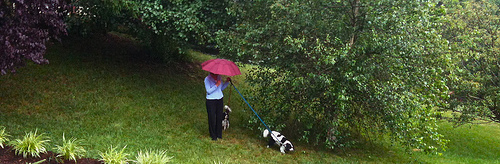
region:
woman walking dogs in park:
[20, 15, 477, 153]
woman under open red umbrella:
[199, 54, 243, 144]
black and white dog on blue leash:
[230, 82, 297, 157]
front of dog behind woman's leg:
[207, 98, 234, 140]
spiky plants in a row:
[2, 121, 174, 161]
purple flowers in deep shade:
[3, 12, 59, 77]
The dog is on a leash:
[258, 118, 295, 154]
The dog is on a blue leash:
[244, 110, 297, 155]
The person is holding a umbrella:
[198, 54, 242, 96]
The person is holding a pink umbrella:
[197, 55, 242, 102]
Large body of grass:
[126, 89, 187, 137]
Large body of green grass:
[145, 95, 189, 137]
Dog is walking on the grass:
[262, 123, 293, 154]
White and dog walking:
[258, 122, 298, 157]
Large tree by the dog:
[252, 5, 457, 156]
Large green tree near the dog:
[256, 8, 453, 162]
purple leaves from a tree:
[0, 0, 78, 75]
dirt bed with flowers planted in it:
[0, 125, 172, 162]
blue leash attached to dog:
[227, 82, 285, 152]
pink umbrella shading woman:
[200, 57, 240, 76]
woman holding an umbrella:
[202, 75, 233, 140]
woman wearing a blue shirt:
[200, 71, 230, 141]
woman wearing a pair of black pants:
[202, 74, 231, 138]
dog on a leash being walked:
[260, 129, 295, 154]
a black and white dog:
[260, 128, 294, 156]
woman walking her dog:
[202, 72, 226, 139]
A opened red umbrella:
[199, 53, 244, 78]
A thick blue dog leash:
[229, 80, 286, 149]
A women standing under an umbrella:
[199, 55, 241, 142]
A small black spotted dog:
[263, 126, 296, 154]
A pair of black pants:
[204, 96, 228, 146]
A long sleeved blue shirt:
[204, 75, 233, 99]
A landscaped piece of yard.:
[2, 128, 169, 162]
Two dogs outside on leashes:
[224, 104, 295, 154]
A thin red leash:
[227, 80, 232, 113]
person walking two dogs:
[200, 57, 293, 153]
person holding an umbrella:
[197, 56, 237, 138]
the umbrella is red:
[196, 55, 236, 82]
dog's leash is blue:
[230, 75, 295, 151]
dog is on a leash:
[226, 75, 291, 155]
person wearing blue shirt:
[204, 58, 232, 143]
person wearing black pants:
[203, 66, 225, 143]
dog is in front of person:
[199, 58, 295, 155]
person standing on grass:
[195, 55, 240, 142]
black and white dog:
[263, 128, 293, 156]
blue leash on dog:
[225, 83, 285, 145]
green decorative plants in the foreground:
[1, 126, 171, 162]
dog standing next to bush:
[256, 114, 299, 154]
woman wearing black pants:
[203, 98, 230, 139]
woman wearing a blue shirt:
[201, 75, 228, 102]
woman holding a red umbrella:
[202, 54, 240, 79]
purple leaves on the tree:
[4, 3, 56, 62]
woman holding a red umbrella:
[198, 54, 240, 96]